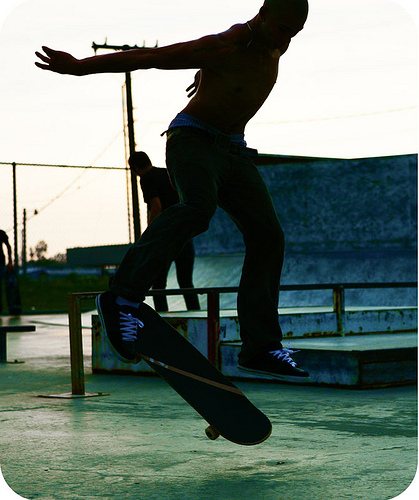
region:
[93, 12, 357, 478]
two people skateboarding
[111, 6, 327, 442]
person doing a skateboard trick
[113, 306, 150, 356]
white shoelaces on sneakers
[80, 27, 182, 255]
wooden electrical pole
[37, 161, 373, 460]
concrete skateboard park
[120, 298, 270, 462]
black skateboard in the air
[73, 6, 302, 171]
man with arms behind him for balance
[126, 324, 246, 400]
diagonal stripe on skateboard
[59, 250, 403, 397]
metal railing to do skateboard tricks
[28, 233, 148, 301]
building in the background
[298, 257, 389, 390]
two steps on the ramp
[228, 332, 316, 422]
foot off of the skateboard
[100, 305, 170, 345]
shoelace is white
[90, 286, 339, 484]
skateboard is in the air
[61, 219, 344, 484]
skateboarder doing a trick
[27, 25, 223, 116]
skater's hands are behind their back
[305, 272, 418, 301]
skateboard railing for tricks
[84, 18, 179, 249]
powerline behind the skaters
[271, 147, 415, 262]
wall of the skate ramp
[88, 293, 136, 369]
white sole of the shoes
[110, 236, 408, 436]
a pair of black shoes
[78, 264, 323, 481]
a pair of black shoes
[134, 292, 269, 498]
A skateboard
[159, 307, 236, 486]
A skateboard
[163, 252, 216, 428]
A skateboard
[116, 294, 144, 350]
White shoelaces in the black shoes.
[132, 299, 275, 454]
Skateboard flying through the air.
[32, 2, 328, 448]
Man performing tricks on his skateboard.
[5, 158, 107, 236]
Chain-link fence in the background.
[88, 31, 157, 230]
Tall telephone pole.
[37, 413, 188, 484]
Ground made of cement to skate on.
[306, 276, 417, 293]
Railing used for performing tricks.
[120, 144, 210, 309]
Man skating in the background.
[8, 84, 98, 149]
Clear sky just before sundown.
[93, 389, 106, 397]
Bolt holding the metal plate in the ground.